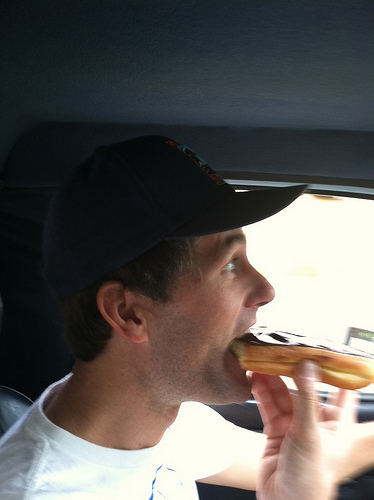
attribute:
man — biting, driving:
[8, 132, 358, 499]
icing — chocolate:
[237, 329, 364, 358]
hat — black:
[41, 129, 309, 296]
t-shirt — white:
[6, 377, 236, 500]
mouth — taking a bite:
[226, 314, 264, 378]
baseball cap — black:
[41, 131, 312, 296]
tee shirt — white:
[2, 371, 242, 498]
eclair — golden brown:
[235, 328, 373, 400]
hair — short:
[56, 237, 196, 368]